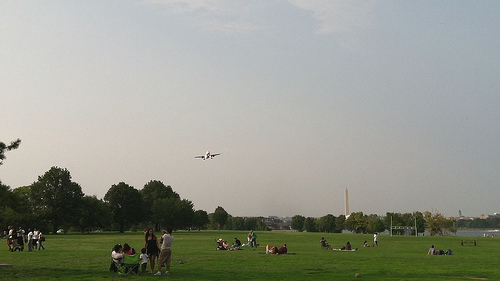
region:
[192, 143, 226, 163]
this is a plane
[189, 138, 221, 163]
the plane is on air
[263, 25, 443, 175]
this is the sky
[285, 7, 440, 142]
the sky is grey in color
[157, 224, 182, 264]
the man is standing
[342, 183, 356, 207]
this is a tower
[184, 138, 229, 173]
plane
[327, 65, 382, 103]
white clouds in blue sky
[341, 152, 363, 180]
white clouds in blue sky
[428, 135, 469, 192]
white clouds in blue sky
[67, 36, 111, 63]
white clouds in blue sky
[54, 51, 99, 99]
white clouds in blue sky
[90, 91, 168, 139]
white clouds in blue sky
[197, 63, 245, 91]
white clouds in blue sky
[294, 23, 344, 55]
white clouds in blue sky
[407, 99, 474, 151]
white clouds in blue sky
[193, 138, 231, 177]
Airplane flying in sky.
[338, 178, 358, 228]
Tall building in distance.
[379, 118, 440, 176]
Sky is clear and grayish blue.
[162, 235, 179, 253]
Person wearing white shirt.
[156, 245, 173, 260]
Person wearing khaki shorts.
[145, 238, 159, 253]
Person wearing black dress.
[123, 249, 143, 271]
Person sitting in green chair.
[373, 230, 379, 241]
Person wearing white shirt.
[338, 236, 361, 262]
Person sitting on blanket.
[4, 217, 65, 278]
People walking in grassy field.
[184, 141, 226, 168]
plane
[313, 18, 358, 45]
white clouds in blue sky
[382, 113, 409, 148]
white clouds in blue sky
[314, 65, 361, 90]
white clouds in blue sky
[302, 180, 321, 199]
white clouds in blue sky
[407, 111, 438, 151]
white clouds in blue sky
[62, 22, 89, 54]
white clouds in blue sky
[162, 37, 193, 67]
white clouds in blue sky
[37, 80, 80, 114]
white clouds in blue sky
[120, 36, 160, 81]
white clouds in blue sky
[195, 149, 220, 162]
Airplane in the sky.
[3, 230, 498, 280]
Large healthy grass field.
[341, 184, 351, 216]
Pointy Washington monument in the distance.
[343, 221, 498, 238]
Blue water in the distance.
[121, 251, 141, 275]
A green chair.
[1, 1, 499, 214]
A grey sky with minimal white clouds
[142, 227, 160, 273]
A brown haired woman in a black tank top and shorts.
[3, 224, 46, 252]
A group of 6 people with mostly white on.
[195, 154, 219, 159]
Left and right wings of an airplane.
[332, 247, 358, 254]
A white blanket on the ground.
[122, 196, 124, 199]
A green leaf on a plant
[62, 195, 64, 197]
A green leaf on a plant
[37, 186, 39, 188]
A green leaf on a plant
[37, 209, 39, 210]
A green leaf on a plant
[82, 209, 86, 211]
A green leaf on a plant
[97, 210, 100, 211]
A green leaf on a plant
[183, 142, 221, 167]
airplane flying in the sky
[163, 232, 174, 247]
person wearing a white shirt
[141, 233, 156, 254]
woman wearing a black dress